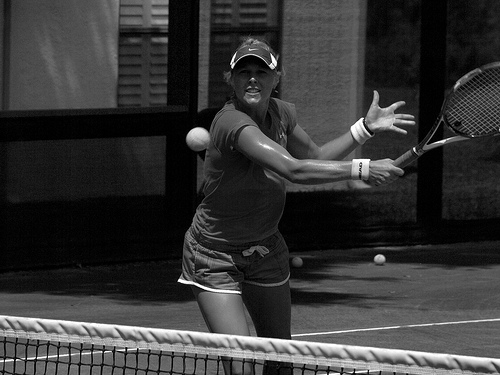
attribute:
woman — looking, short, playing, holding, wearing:
[175, 36, 416, 369]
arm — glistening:
[234, 120, 370, 185]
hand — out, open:
[364, 89, 416, 139]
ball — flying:
[187, 126, 211, 154]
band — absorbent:
[350, 156, 371, 182]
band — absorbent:
[352, 115, 376, 149]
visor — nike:
[228, 40, 280, 75]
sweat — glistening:
[240, 125, 350, 185]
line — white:
[7, 311, 496, 366]